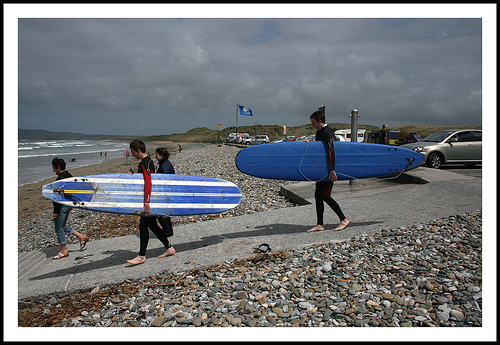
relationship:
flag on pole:
[238, 105, 252, 118] [233, 104, 240, 138]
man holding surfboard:
[306, 109, 350, 233] [235, 138, 428, 180]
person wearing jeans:
[47, 157, 89, 258] [52, 201, 76, 248]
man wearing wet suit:
[125, 139, 177, 265] [133, 158, 172, 254]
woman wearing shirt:
[150, 146, 178, 239] [155, 160, 175, 174]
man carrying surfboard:
[306, 109, 350, 233] [235, 138, 428, 180]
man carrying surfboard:
[125, 139, 177, 265] [39, 170, 244, 217]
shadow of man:
[224, 216, 381, 239] [306, 109, 350, 233]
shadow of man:
[30, 234, 221, 282] [125, 139, 177, 265]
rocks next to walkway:
[19, 210, 484, 326] [18, 176, 482, 305]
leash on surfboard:
[297, 139, 412, 188] [235, 138, 428, 180]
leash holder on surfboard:
[403, 154, 414, 171] [235, 138, 428, 180]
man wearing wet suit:
[306, 109, 350, 233] [310, 127, 345, 223]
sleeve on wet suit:
[139, 165, 155, 205] [133, 158, 172, 254]